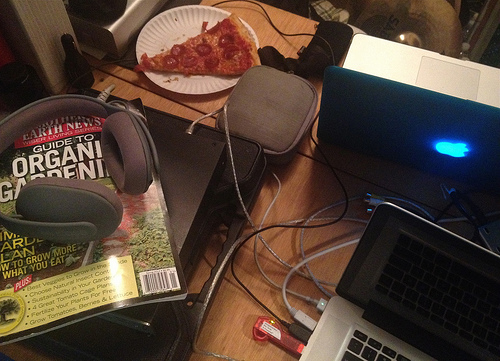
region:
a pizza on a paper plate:
[132, 3, 262, 98]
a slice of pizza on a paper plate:
[133, 5, 263, 90]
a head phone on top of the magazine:
[8, 88, 163, 245]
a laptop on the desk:
[291, 197, 495, 359]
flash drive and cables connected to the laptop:
[246, 292, 331, 358]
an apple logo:
[426, 133, 473, 163]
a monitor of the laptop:
[332, 199, 497, 359]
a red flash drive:
[247, 310, 302, 357]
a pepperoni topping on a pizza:
[194, 40, 211, 55]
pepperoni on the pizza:
[164, 43, 200, 70]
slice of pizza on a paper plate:
[133, 3, 264, 104]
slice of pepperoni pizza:
[129, 7, 263, 84]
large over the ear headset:
[0, 90, 167, 252]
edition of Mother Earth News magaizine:
[0, 92, 199, 350]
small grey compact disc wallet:
[212, 59, 323, 164]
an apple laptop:
[315, 23, 498, 198]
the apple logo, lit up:
[420, 128, 480, 166]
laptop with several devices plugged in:
[238, 191, 493, 359]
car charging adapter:
[55, 24, 98, 91]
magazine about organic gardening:
[1, 91, 195, 359]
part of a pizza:
[191, 65, 213, 78]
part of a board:
[370, 234, 402, 284]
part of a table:
[221, 315, 247, 352]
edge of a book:
[132, 274, 172, 329]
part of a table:
[229, 290, 246, 307]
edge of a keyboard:
[328, 273, 350, 318]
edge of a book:
[169, 259, 224, 341]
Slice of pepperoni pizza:
[132, 3, 263, 100]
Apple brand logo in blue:
[419, 118, 484, 183]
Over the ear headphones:
[3, 80, 167, 269]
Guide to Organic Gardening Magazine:
[0, 89, 192, 349]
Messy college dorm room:
[0, 26, 497, 358]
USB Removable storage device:
[244, 309, 315, 359]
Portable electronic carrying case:
[207, 61, 325, 163]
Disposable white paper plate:
[135, 25, 271, 98]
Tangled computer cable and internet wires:
[189, 139, 418, 359]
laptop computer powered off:
[298, 196, 495, 359]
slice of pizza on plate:
[131, 10, 269, 82]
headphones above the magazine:
[0, 91, 164, 242]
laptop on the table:
[290, 198, 498, 360]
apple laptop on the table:
[317, 31, 498, 191]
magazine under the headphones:
[0, 103, 187, 344]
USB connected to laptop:
[249, 317, 309, 354]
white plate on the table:
[136, 5, 259, 97]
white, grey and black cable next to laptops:
[197, 108, 498, 359]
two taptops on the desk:
[295, 31, 498, 359]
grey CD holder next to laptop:
[215, 61, 320, 165]